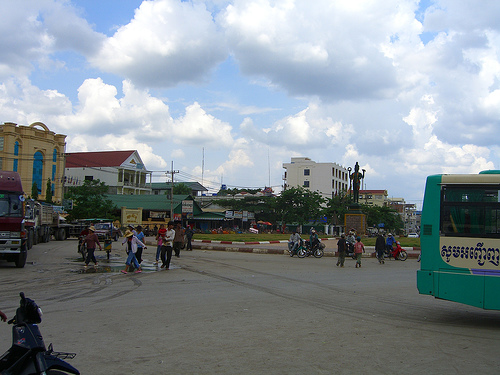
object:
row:
[63, 141, 281, 226]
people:
[77, 222, 105, 269]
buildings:
[62, 194, 206, 230]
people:
[370, 233, 388, 266]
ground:
[0, 230, 500, 375]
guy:
[306, 228, 323, 250]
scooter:
[294, 245, 329, 257]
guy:
[288, 227, 302, 256]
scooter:
[285, 240, 308, 260]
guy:
[385, 229, 398, 258]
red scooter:
[388, 236, 412, 263]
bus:
[413, 169, 500, 314]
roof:
[66, 147, 135, 168]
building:
[2, 118, 70, 204]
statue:
[347, 158, 370, 202]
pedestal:
[341, 157, 366, 240]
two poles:
[346, 169, 368, 200]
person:
[117, 229, 147, 275]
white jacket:
[118, 234, 148, 256]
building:
[278, 152, 352, 238]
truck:
[2, 164, 30, 268]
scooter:
[2, 288, 88, 374]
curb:
[194, 244, 289, 253]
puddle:
[68, 251, 174, 277]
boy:
[352, 232, 370, 268]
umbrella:
[254, 216, 276, 229]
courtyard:
[192, 222, 427, 246]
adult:
[155, 219, 179, 273]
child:
[154, 221, 171, 244]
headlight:
[36, 302, 44, 319]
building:
[67, 147, 150, 193]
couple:
[333, 230, 369, 270]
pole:
[165, 159, 180, 199]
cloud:
[0, 0, 500, 196]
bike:
[294, 243, 323, 259]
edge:
[193, 241, 285, 259]